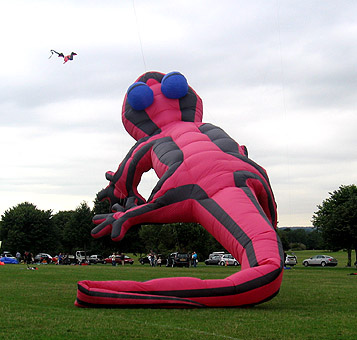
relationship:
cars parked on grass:
[2, 249, 335, 269] [15, 308, 310, 337]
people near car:
[191, 250, 199, 268] [300, 253, 337, 266]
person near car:
[14, 250, 20, 262] [284, 252, 299, 266]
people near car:
[110, 252, 118, 267] [217, 252, 239, 266]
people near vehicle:
[110, 252, 118, 267] [203, 252, 223, 264]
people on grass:
[56, 251, 63, 263] [1, 248, 353, 339]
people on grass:
[118, 251, 125, 264] [1, 248, 353, 339]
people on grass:
[110, 252, 115, 263] [1, 248, 353, 339]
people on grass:
[156, 257, 162, 266] [1, 248, 353, 339]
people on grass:
[191, 250, 199, 268] [1, 248, 353, 339]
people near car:
[118, 251, 126, 267] [101, 252, 135, 265]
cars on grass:
[1, 248, 341, 270] [4, 263, 355, 338]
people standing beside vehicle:
[156, 255, 163, 267] [170, 251, 190, 266]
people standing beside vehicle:
[156, 255, 163, 267] [137, 253, 165, 266]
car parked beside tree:
[103, 254, 131, 262] [312, 185, 354, 267]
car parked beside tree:
[220, 252, 236, 264] [312, 185, 354, 267]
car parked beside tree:
[284, 252, 296, 264] [312, 185, 354, 267]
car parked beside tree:
[298, 253, 336, 265] [312, 185, 354, 267]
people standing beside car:
[110, 252, 118, 267] [98, 249, 135, 263]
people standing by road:
[191, 250, 199, 268] [6, 251, 344, 265]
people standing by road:
[118, 251, 126, 267] [6, 251, 344, 265]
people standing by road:
[110, 252, 118, 267] [6, 251, 344, 265]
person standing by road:
[146, 252, 151, 264] [6, 251, 344, 265]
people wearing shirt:
[191, 250, 199, 268] [193, 253, 198, 258]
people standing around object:
[34, 251, 200, 262] [2, 251, 18, 266]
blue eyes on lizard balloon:
[124, 69, 191, 108] [75, 70, 287, 311]